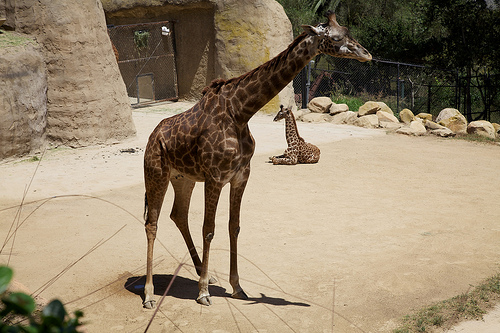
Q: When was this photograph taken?
A: Daytime.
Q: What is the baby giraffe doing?
A: Laying down.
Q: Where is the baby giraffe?
A: Behind the adult giraffe.